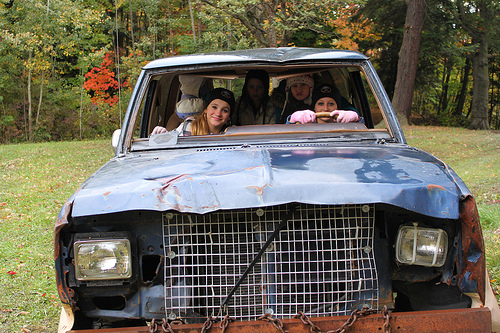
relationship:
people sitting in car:
[196, 83, 354, 125] [67, 52, 496, 321]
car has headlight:
[67, 52, 496, 321] [396, 221, 464, 283]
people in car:
[196, 83, 354, 125] [67, 52, 496, 321]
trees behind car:
[19, 15, 499, 103] [67, 52, 496, 321]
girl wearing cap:
[288, 90, 363, 125] [315, 82, 333, 95]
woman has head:
[180, 92, 243, 137] [207, 92, 231, 130]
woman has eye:
[180, 92, 243, 137] [212, 104, 229, 111]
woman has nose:
[180, 92, 243, 137] [216, 110, 224, 118]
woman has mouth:
[180, 92, 243, 137] [208, 115, 229, 122]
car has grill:
[67, 52, 496, 321] [171, 202, 369, 300]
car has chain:
[67, 52, 496, 321] [159, 304, 392, 332]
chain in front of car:
[159, 304, 392, 332] [67, 52, 496, 321]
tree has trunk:
[374, 3, 466, 130] [397, 34, 424, 106]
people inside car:
[196, 83, 354, 125] [67, 52, 496, 321]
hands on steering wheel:
[294, 112, 363, 120] [283, 108, 375, 128]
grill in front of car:
[171, 202, 369, 300] [67, 52, 496, 321]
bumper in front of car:
[150, 309, 497, 332] [67, 52, 496, 321]